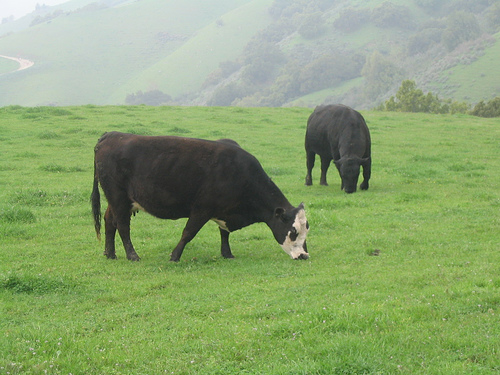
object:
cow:
[305, 100, 373, 194]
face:
[284, 198, 312, 264]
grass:
[0, 102, 500, 374]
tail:
[88, 141, 109, 240]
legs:
[171, 217, 209, 262]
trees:
[375, 77, 470, 111]